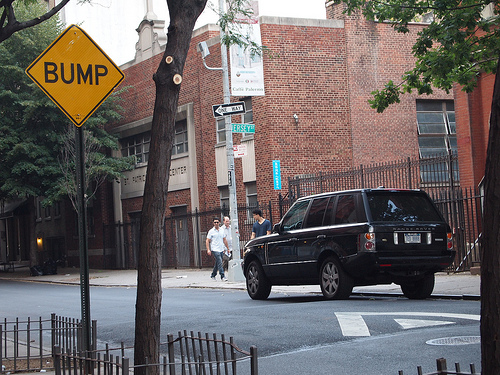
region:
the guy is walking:
[206, 214, 233, 268]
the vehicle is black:
[288, 223, 320, 258]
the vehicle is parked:
[311, 230, 343, 257]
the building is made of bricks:
[313, 116, 350, 160]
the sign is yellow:
[53, 36, 105, 99]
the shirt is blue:
[253, 221, 267, 236]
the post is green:
[73, 191, 93, 229]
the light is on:
[31, 233, 46, 253]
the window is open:
[415, 104, 447, 143]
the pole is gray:
[222, 200, 242, 234]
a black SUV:
[240, 189, 455, 303]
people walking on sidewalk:
[204, 211, 268, 278]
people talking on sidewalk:
[204, 212, 285, 282]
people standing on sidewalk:
[204, 204, 278, 282]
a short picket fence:
[1, 310, 496, 369]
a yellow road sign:
[26, 20, 124, 125]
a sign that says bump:
[28, 23, 123, 123]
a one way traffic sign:
[210, 95, 245, 118]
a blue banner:
[267, 155, 283, 192]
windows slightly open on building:
[414, 98, 457, 181]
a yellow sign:
[33, 36, 108, 128]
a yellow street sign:
[31, 40, 126, 122]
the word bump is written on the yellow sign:
[36, 52, 116, 106]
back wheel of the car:
[318, 264, 349, 293]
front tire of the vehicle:
[244, 263, 271, 296]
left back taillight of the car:
[359, 230, 379, 250]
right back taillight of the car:
[445, 228, 456, 251]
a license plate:
[402, 230, 423, 242]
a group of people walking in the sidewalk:
[206, 211, 236, 278]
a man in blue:
[243, 207, 270, 234]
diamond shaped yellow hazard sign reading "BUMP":
[27, 24, 130, 126]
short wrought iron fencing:
[0, 314, 260, 373]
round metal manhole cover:
[426, 337, 478, 347]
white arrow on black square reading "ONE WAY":
[209, 100, 247, 118]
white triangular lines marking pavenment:
[332, 304, 480, 334]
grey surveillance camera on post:
[195, 42, 227, 74]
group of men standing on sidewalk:
[203, 210, 272, 287]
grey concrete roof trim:
[261, 16, 345, 28]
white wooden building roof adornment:
[120, 1, 169, 62]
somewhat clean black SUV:
[240, 188, 456, 304]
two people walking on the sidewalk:
[202, 215, 233, 283]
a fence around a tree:
[54, 331, 264, 373]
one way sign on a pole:
[212, 97, 246, 119]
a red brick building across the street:
[42, 11, 460, 275]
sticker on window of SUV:
[385, 199, 402, 216]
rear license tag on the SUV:
[402, 232, 424, 243]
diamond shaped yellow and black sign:
[27, 22, 126, 129]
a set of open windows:
[417, 98, 460, 184]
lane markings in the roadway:
[331, 308, 482, 339]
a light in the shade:
[35, 234, 42, 249]